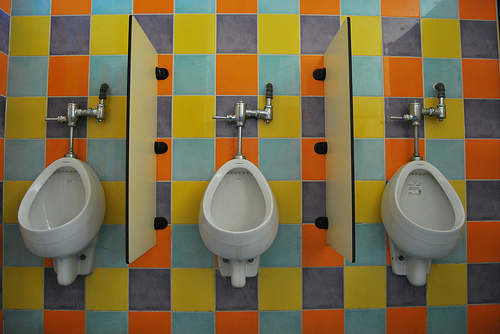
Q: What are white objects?
A: Urinals.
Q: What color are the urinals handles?
A: Silver.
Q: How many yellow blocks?
A: 24.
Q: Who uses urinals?
A: Male humans.